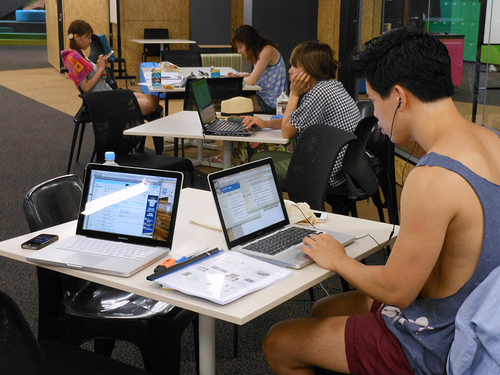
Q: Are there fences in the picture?
A: No, there are no fences.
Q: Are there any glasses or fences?
A: No, there are no fences or glasses.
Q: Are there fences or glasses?
A: No, there are no fences or glasses.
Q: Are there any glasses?
A: No, there are no glasses.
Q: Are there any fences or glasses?
A: No, there are no glasses or fences.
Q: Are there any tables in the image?
A: Yes, there is a table.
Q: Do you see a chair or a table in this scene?
A: Yes, there is a table.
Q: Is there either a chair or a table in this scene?
A: Yes, there is a table.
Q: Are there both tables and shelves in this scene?
A: No, there is a table but no shelves.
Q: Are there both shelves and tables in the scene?
A: No, there is a table but no shelves.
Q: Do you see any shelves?
A: No, there are no shelves.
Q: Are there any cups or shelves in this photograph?
A: No, there are no shelves or cups.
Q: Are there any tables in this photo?
A: Yes, there is a table.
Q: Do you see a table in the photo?
A: Yes, there is a table.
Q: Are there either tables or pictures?
A: Yes, there is a table.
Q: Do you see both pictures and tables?
A: No, there is a table but no pictures.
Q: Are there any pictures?
A: No, there are no pictures.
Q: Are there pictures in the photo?
A: No, there are no pictures.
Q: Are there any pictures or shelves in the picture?
A: No, there are no pictures or shelves.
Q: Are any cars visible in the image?
A: No, there are no cars.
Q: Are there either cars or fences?
A: No, there are no cars or fences.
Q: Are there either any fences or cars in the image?
A: No, there are no cars or fences.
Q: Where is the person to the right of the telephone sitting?
A: The person is sitting at the table.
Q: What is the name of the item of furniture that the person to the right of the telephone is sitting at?
A: The piece of furniture is a table.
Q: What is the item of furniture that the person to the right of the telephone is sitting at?
A: The piece of furniture is a table.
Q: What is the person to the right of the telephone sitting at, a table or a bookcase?
A: The person is sitting at a table.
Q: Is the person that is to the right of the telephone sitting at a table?
A: Yes, the person is sitting at a table.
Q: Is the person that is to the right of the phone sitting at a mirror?
A: No, the person is sitting at a table.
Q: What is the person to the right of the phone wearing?
A: The person is wearing a shirt.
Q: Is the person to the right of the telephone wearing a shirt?
A: Yes, the person is wearing a shirt.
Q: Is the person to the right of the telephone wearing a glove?
A: No, the person is wearing a shirt.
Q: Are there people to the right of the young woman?
A: Yes, there is a person to the right of the woman.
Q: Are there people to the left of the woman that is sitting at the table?
A: No, the person is to the right of the woman.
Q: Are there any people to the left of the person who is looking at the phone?
A: No, the person is to the right of the woman.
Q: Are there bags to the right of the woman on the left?
A: No, there is a person to the right of the woman.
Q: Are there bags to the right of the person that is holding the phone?
A: No, there is a person to the right of the woman.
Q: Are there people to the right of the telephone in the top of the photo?
A: Yes, there is a person to the right of the telephone.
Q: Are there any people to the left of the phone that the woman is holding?
A: No, the person is to the right of the phone.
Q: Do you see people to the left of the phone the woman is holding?
A: No, the person is to the right of the phone.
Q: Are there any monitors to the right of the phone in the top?
A: No, there is a person to the right of the phone.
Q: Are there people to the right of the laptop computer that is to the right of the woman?
A: Yes, there is a person to the right of the laptop.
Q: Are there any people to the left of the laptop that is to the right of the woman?
A: No, the person is to the right of the laptop.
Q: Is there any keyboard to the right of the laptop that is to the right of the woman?
A: No, there is a person to the right of the laptop.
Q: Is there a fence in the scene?
A: No, there are no fences.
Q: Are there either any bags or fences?
A: No, there are no fences or bags.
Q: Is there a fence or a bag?
A: No, there are no fences or bags.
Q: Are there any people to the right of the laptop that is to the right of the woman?
A: Yes, there is a person to the right of the laptop.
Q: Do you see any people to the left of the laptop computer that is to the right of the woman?
A: No, the person is to the right of the laptop.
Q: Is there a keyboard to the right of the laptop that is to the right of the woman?
A: No, there is a person to the right of the laptop computer.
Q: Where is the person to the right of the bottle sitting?
A: The person is sitting at the table.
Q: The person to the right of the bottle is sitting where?
A: The person is sitting at the table.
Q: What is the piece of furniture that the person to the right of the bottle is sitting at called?
A: The piece of furniture is a table.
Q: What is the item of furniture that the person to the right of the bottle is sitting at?
A: The piece of furniture is a table.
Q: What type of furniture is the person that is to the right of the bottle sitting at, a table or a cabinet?
A: The person is sitting at a table.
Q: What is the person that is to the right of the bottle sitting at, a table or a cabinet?
A: The person is sitting at a table.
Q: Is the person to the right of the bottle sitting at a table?
A: Yes, the person is sitting at a table.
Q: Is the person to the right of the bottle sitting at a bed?
A: No, the person is sitting at a table.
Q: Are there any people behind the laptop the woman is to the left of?
A: Yes, there is a person behind the laptop.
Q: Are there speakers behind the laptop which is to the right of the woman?
A: No, there is a person behind the laptop.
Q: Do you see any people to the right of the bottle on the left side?
A: Yes, there is a person to the right of the bottle.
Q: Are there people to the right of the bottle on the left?
A: Yes, there is a person to the right of the bottle.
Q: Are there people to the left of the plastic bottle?
A: No, the person is to the right of the bottle.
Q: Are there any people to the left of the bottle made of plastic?
A: No, the person is to the right of the bottle.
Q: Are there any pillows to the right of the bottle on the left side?
A: No, there is a person to the right of the bottle.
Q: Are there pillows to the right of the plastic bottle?
A: No, there is a person to the right of the bottle.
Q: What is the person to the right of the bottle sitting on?
A: The person is sitting on the chair.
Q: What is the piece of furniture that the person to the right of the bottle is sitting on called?
A: The piece of furniture is a chair.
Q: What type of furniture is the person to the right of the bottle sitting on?
A: The person is sitting on the chair.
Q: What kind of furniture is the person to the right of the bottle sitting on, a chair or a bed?
A: The person is sitting on a chair.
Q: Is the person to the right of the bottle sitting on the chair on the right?
A: Yes, the person is sitting on the chair.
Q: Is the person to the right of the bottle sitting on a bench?
A: No, the person is sitting on the chair.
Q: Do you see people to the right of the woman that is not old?
A: Yes, there is a person to the right of the woman.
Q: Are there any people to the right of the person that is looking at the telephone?
A: Yes, there is a person to the right of the woman.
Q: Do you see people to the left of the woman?
A: No, the person is to the right of the woman.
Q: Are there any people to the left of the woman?
A: No, the person is to the right of the woman.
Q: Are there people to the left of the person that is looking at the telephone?
A: No, the person is to the right of the woman.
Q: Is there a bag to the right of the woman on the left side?
A: No, there is a person to the right of the woman.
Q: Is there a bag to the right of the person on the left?
A: No, there is a person to the right of the woman.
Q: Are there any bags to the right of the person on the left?
A: No, there is a person to the right of the woman.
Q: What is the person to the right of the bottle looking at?
A: The person is looking at the laptop.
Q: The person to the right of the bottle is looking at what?
A: The person is looking at the laptop.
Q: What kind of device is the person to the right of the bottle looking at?
A: The person is looking at the laptop.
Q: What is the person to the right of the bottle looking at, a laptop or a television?
A: The person is looking at a laptop.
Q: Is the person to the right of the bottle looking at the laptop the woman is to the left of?
A: Yes, the person is looking at the laptop.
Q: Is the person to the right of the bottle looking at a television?
A: No, the person is looking at the laptop.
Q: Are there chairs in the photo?
A: Yes, there is a chair.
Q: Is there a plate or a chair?
A: Yes, there is a chair.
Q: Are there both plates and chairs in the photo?
A: No, there is a chair but no plates.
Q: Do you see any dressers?
A: No, there are no dressers.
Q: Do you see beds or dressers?
A: No, there are no dressers or beds.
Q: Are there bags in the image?
A: No, there are no bags.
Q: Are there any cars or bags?
A: No, there are no bags or cars.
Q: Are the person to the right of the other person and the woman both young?
A: Yes, both the person and the woman are young.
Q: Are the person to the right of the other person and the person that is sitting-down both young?
A: Yes, both the person and the woman are young.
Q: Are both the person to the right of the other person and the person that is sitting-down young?
A: Yes, both the person and the woman are young.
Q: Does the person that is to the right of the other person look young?
A: Yes, the person is young.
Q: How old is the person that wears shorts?
A: The person is young.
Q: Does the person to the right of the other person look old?
A: No, the person is young.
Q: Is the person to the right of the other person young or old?
A: The person is young.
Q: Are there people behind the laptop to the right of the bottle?
A: Yes, there is a person behind the laptop.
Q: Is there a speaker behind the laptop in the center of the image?
A: No, there is a person behind the laptop computer.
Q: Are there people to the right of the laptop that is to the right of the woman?
A: Yes, there is a person to the right of the laptop computer.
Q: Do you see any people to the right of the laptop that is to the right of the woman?
A: Yes, there is a person to the right of the laptop computer.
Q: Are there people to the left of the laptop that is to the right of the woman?
A: No, the person is to the right of the laptop.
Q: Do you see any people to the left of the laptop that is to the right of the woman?
A: No, the person is to the right of the laptop.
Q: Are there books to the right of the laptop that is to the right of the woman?
A: No, there is a person to the right of the laptop computer.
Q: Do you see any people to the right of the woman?
A: Yes, there is a person to the right of the woman.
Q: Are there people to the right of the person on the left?
A: Yes, there is a person to the right of the woman.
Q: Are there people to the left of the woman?
A: No, the person is to the right of the woman.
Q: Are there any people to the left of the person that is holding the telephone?
A: No, the person is to the right of the woman.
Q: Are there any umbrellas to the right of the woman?
A: No, there is a person to the right of the woman.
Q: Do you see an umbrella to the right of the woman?
A: No, there is a person to the right of the woman.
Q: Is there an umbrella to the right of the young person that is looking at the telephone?
A: No, there is a person to the right of the woman.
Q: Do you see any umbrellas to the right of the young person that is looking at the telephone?
A: No, there is a person to the right of the woman.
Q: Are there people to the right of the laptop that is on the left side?
A: Yes, there is a person to the right of the laptop.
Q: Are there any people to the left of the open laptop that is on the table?
A: No, the person is to the right of the laptop.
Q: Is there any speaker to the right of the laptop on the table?
A: No, there is a person to the right of the laptop.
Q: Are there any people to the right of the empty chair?
A: Yes, there is a person to the right of the chair.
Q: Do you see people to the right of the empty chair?
A: Yes, there is a person to the right of the chair.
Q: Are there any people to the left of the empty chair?
A: No, the person is to the right of the chair.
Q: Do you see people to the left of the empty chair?
A: No, the person is to the right of the chair.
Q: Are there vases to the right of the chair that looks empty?
A: No, there is a person to the right of the chair.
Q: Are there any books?
A: No, there are no books.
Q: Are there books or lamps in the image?
A: No, there are no books or lamps.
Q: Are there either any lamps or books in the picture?
A: No, there are no books or lamps.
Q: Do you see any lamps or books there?
A: No, there are no books or lamps.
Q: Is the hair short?
A: Yes, the hair is short.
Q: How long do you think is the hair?
A: The hair is short.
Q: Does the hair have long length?
A: No, the hair is short.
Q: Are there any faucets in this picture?
A: No, there are no faucets.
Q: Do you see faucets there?
A: No, there are no faucets.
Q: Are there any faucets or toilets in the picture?
A: No, there are no faucets or toilets.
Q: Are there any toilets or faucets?
A: No, there are no faucets or toilets.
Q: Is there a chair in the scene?
A: Yes, there is a chair.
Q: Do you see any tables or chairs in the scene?
A: Yes, there is a chair.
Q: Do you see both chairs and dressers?
A: No, there is a chair but no dressers.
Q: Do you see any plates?
A: No, there are no plates.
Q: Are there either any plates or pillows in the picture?
A: No, there are no plates or pillows.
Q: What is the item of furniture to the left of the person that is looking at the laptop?
A: The piece of furniture is a chair.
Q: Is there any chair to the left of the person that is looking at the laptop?
A: Yes, there is a chair to the left of the person.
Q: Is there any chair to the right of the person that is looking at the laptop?
A: No, the chair is to the left of the person.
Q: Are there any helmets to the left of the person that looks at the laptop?
A: No, there is a chair to the left of the person.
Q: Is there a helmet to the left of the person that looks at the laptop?
A: No, there is a chair to the left of the person.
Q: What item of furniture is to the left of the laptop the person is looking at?
A: The piece of furniture is a chair.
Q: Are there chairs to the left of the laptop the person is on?
A: Yes, there is a chair to the left of the laptop.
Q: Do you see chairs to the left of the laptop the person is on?
A: Yes, there is a chair to the left of the laptop.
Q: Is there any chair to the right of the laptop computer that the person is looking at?
A: No, the chair is to the left of the laptop.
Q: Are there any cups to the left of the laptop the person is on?
A: No, there is a chair to the left of the laptop.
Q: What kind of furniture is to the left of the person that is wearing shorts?
A: The piece of furniture is a chair.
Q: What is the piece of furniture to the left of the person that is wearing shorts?
A: The piece of furniture is a chair.